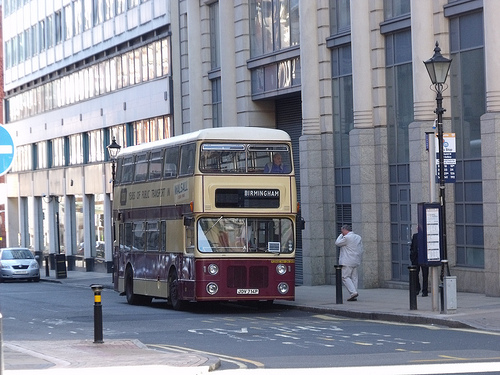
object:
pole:
[89, 282, 104, 344]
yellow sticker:
[93, 294, 101, 303]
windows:
[197, 143, 249, 175]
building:
[166, 0, 498, 298]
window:
[289, 56, 303, 89]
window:
[286, 0, 299, 48]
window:
[390, 26, 411, 67]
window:
[391, 0, 412, 19]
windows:
[194, 215, 296, 257]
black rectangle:
[213, 188, 281, 209]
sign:
[0, 123, 19, 180]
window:
[248, 65, 265, 98]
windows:
[155, 116, 163, 142]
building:
[0, 0, 174, 279]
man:
[332, 223, 365, 302]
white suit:
[332, 230, 366, 300]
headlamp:
[272, 261, 289, 276]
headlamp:
[275, 280, 289, 297]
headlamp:
[205, 262, 222, 276]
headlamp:
[205, 281, 220, 297]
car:
[0, 247, 43, 283]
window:
[260, 61, 278, 95]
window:
[159, 36, 171, 80]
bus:
[106, 125, 304, 310]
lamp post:
[420, 40, 452, 312]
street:
[0, 280, 499, 373]